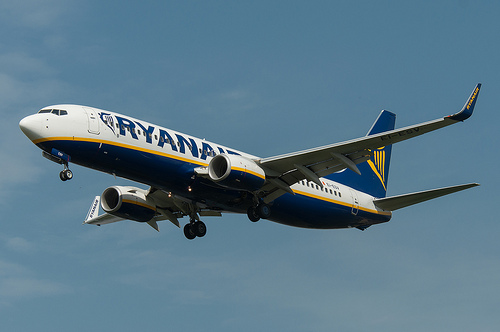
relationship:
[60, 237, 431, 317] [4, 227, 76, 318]
sky has clouds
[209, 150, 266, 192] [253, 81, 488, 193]
jet engine under wing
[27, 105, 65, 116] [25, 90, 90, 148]
windows on cockpit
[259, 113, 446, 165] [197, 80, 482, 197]
edge of wing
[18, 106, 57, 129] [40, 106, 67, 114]
nose with cockpit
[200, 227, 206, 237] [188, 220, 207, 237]
part of wheel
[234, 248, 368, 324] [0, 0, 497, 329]
part of sky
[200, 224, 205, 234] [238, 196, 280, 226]
part of wheel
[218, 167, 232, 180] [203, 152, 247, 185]
part of an engine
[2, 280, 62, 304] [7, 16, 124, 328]
part of a cloud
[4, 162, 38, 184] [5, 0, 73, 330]
part of a cloud